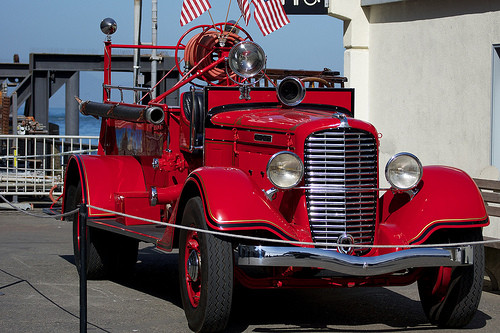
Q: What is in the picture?
A: A truck.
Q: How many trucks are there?
A: One.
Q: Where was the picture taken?
A: By the ocean.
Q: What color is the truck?
A: Red.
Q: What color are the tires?
A: Black.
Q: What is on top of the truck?
A: American flags.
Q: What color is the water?
A: Blue.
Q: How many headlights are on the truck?
A: Two.